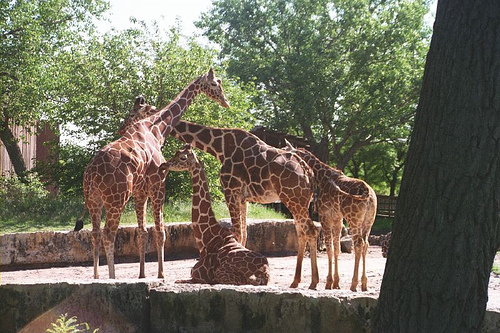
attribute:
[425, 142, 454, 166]
bark — is brown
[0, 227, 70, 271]
wall — tan, tall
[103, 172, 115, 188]
spot — brown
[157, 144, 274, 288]
giraffe — lying, laying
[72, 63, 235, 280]
giraffe — standing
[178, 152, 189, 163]
eye — dark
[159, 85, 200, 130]
neck — long